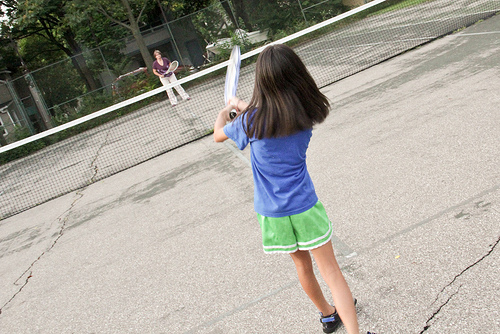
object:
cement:
[2, 139, 146, 319]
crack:
[30, 190, 79, 260]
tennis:
[122, 10, 372, 331]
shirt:
[152, 58, 175, 78]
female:
[210, 35, 366, 334]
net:
[0, 0, 438, 164]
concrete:
[137, 209, 241, 290]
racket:
[164, 60, 180, 76]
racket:
[223, 44, 242, 120]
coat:
[151, 59, 177, 78]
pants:
[158, 69, 191, 106]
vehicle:
[112, 67, 200, 97]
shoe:
[318, 299, 361, 334]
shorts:
[256, 201, 330, 255]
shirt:
[221, 103, 319, 217]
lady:
[151, 50, 192, 107]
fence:
[2, 0, 273, 116]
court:
[0, 0, 499, 334]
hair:
[244, 45, 326, 142]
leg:
[286, 251, 337, 318]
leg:
[303, 239, 358, 331]